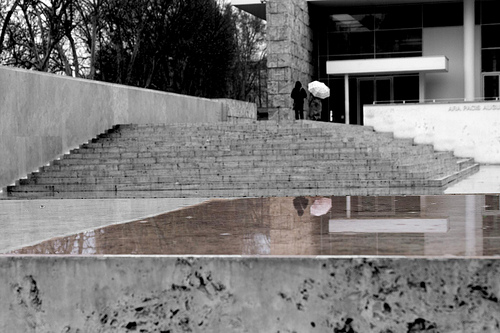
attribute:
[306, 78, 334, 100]
umbrella — open, white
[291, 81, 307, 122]
person — standing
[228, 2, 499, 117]
building — white, rectangle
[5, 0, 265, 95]
trees — tangle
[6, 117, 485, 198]
steps — gray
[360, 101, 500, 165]
wall — light, rough, white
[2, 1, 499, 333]
photo — black, white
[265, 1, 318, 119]
column — textured, single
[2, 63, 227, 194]
wall — gray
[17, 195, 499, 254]
tile — brown, large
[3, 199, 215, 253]
tile — gray, large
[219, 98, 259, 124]
wall — stone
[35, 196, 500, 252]
water — smooth, large